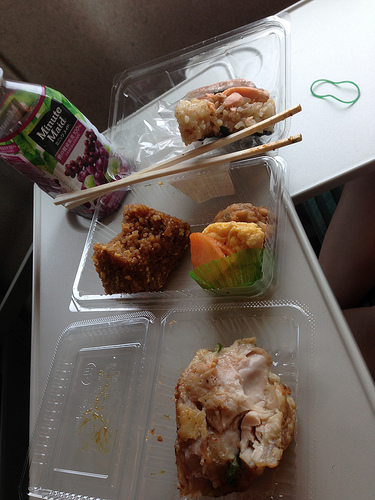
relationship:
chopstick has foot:
[56, 133, 298, 203] [258, 133, 300, 154]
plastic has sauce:
[13, 303, 318, 500] [89, 374, 112, 456]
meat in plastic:
[175, 338, 298, 498] [13, 303, 318, 500]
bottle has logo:
[2, 70, 136, 219] [30, 99, 76, 158]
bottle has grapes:
[2, 70, 136, 219] [63, 127, 108, 179]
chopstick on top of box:
[56, 133, 298, 203] [68, 12, 295, 298]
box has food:
[68, 12, 295, 298] [175, 80, 276, 140]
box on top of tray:
[68, 12, 295, 298] [29, 59, 374, 499]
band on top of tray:
[308, 77, 359, 104] [29, 59, 374, 499]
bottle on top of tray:
[2, 70, 136, 219] [29, 59, 374, 499]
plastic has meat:
[13, 303, 318, 500] [175, 338, 298, 498]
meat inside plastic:
[175, 338, 298, 498] [13, 303, 318, 500]